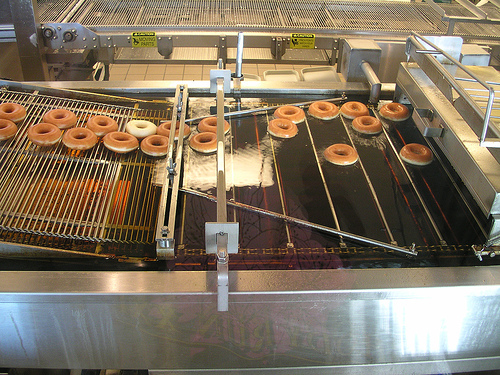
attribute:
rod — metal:
[199, 69, 236, 275]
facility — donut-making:
[3, 1, 495, 371]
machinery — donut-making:
[8, 39, 498, 374]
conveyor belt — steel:
[1, 87, 187, 254]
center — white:
[114, 134, 131, 144]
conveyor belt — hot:
[0, 88, 175, 246]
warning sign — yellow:
[130, 27, 157, 47]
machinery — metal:
[398, 65, 475, 171]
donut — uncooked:
[127, 114, 157, 140]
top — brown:
[311, 99, 337, 115]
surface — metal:
[7, 289, 499, 371]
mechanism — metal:
[402, 37, 499, 265]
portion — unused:
[1, 1, 499, 69]